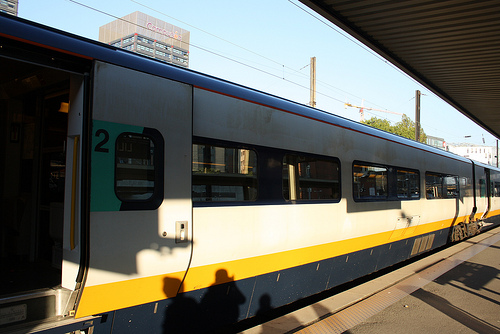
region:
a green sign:
[70, 113, 163, 227]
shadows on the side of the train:
[145, 250, 269, 324]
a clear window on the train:
[100, 143, 355, 215]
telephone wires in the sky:
[107, 1, 313, 68]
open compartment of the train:
[2, 67, 119, 332]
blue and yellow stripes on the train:
[132, 205, 479, 331]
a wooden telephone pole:
[298, 42, 325, 129]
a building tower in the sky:
[84, 10, 228, 62]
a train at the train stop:
[6, 5, 480, 327]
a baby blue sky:
[227, 16, 332, 53]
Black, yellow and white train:
[82, 87, 468, 264]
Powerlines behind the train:
[302, 63, 450, 149]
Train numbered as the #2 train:
[72, 112, 182, 228]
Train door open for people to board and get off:
[17, 55, 122, 308]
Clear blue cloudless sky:
[256, 57, 439, 122]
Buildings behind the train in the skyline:
[332, 96, 493, 164]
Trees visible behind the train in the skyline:
[338, 85, 420, 140]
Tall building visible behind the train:
[86, 15, 221, 76]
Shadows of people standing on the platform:
[137, 260, 409, 325]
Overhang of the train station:
[268, 4, 493, 88]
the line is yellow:
[258, 257, 268, 272]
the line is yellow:
[250, 263, 262, 269]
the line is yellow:
[247, 263, 253, 268]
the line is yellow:
[254, 267, 261, 269]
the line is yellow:
[244, 263, 252, 275]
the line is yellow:
[234, 260, 242, 268]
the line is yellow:
[233, 262, 242, 275]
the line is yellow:
[219, 271, 234, 283]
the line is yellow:
[256, 260, 264, 279]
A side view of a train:
[0, 74, 497, 305]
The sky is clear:
[173, 3, 488, 170]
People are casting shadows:
[134, 258, 279, 328]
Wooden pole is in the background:
[299, 55, 326, 113]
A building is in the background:
[87, 6, 204, 76]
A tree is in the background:
[353, 110, 430, 145]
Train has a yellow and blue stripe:
[76, 213, 480, 332]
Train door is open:
[4, 47, 89, 303]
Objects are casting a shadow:
[398, 246, 498, 328]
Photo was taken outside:
[4, 1, 498, 333]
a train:
[174, 134, 295, 279]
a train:
[216, 196, 417, 316]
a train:
[206, 206, 294, 291]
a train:
[171, 187, 331, 312]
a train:
[156, 160, 264, 325]